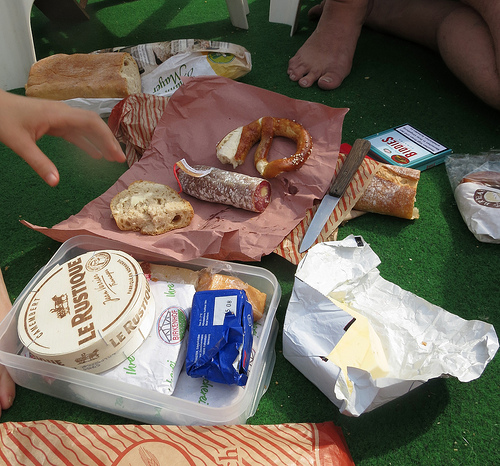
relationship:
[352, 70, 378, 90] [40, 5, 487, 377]
crumb on ground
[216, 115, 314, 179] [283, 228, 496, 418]
bread on paper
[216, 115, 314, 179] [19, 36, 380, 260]
bread on paper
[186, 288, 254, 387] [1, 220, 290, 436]
blue food in a container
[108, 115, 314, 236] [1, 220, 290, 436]
food in a container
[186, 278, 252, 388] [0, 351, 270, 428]
blue food in a container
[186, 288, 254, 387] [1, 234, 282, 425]
blue food in a container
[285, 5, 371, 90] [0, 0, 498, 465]
foot on a surface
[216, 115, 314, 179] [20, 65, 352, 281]
bread on paper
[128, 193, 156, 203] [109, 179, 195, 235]
butter on bread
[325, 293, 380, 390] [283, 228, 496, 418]
butter in paper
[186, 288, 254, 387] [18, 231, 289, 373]
blue food in container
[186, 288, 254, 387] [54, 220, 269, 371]
blue food in container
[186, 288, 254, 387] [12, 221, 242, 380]
blue food in container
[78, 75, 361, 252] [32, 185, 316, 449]
food in container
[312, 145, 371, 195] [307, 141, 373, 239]
handle on knife